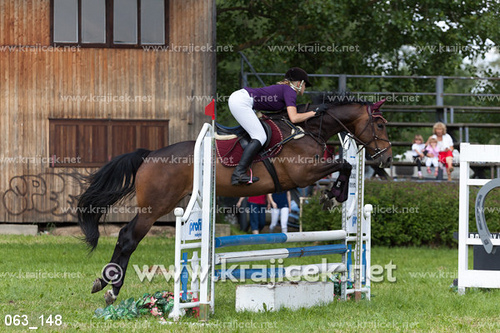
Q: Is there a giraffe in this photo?
A: No, there are no giraffes.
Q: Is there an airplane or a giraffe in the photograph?
A: No, there are no giraffes or airplanes.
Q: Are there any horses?
A: Yes, there is a horse.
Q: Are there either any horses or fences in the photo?
A: Yes, there is a horse.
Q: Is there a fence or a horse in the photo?
A: Yes, there is a horse.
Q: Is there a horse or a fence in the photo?
A: Yes, there is a horse.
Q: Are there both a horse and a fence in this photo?
A: Yes, there are both a horse and a fence.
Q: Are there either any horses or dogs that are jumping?
A: Yes, the horse is jumping.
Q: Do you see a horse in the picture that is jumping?
A: Yes, there is a horse that is jumping.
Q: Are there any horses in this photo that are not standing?
A: Yes, there is a horse that is jumping.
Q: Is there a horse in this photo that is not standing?
A: Yes, there is a horse that is jumping.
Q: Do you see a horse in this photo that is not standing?
A: Yes, there is a horse that is jumping .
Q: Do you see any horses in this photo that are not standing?
A: Yes, there is a horse that is jumping .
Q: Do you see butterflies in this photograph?
A: No, there are no butterflies.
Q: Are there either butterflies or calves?
A: No, there are no butterflies or calves.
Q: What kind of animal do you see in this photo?
A: The animal is a horse.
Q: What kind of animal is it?
A: The animal is a horse.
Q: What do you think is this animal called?
A: This is a horse.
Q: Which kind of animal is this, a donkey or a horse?
A: This is a horse.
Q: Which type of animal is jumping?
A: The animal is a horse.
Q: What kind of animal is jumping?
A: The animal is a horse.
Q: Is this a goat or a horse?
A: This is a horse.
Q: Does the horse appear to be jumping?
A: Yes, the horse is jumping.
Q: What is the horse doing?
A: The horse is jumping.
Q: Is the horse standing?
A: No, the horse is jumping.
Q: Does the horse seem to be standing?
A: No, the horse is jumping.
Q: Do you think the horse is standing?
A: No, the horse is jumping.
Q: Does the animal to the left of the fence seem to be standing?
A: No, the horse is jumping.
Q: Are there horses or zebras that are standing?
A: No, there is a horse but it is jumping.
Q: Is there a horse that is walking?
A: No, there is a horse but it is jumping.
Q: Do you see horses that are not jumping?
A: No, there is a horse but it is jumping.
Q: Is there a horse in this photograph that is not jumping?
A: No, there is a horse but it is jumping.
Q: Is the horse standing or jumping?
A: The horse is jumping.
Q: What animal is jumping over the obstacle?
A: The horse is jumping over the obstacle.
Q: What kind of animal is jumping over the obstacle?
A: The animal is a horse.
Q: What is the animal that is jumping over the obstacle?
A: The animal is a horse.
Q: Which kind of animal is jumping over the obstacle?
A: The animal is a horse.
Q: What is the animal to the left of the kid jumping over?
A: The horse is jumping over the obstacle.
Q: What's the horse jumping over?
A: The horse is jumping over the obstacle.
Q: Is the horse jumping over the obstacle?
A: Yes, the horse is jumping over the obstacle.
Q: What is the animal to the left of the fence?
A: The animal is a horse.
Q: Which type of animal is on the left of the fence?
A: The animal is a horse.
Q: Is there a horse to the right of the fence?
A: No, the horse is to the left of the fence.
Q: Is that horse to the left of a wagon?
A: No, the horse is to the left of the fence.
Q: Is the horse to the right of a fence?
A: No, the horse is to the left of a fence.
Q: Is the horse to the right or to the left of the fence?
A: The horse is to the left of the fence.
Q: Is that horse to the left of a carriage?
A: No, the horse is to the left of a child.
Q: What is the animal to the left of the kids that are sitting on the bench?
A: The animal is a horse.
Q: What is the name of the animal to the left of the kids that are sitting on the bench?
A: The animal is a horse.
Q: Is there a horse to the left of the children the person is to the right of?
A: Yes, there is a horse to the left of the kids.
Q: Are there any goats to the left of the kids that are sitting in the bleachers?
A: No, there is a horse to the left of the children.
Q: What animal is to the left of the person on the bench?
A: The animal is a horse.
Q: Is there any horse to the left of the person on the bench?
A: Yes, there is a horse to the left of the person.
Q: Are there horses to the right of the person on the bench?
A: No, the horse is to the left of the person.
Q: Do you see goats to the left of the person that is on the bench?
A: No, there is a horse to the left of the person.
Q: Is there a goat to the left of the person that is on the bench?
A: No, there is a horse to the left of the person.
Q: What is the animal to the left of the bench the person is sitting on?
A: The animal is a horse.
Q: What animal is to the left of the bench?
A: The animal is a horse.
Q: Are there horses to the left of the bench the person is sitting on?
A: Yes, there is a horse to the left of the bench.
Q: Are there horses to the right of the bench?
A: No, the horse is to the left of the bench.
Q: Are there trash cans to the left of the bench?
A: No, there is a horse to the left of the bench.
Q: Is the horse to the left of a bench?
A: Yes, the horse is to the left of a bench.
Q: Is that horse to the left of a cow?
A: No, the horse is to the left of a bench.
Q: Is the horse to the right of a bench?
A: No, the horse is to the left of a bench.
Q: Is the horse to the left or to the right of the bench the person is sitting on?
A: The horse is to the left of the bench.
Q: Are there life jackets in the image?
A: No, there are no life jackets.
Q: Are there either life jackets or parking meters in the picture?
A: No, there are no life jackets or parking meters.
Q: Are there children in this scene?
A: Yes, there is a child.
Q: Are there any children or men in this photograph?
A: Yes, there is a child.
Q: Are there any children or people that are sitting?
A: Yes, the child is sitting.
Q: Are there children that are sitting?
A: Yes, there is a child that is sitting.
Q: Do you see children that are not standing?
A: Yes, there is a child that is sitting .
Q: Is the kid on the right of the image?
A: Yes, the kid is on the right of the image.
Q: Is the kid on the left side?
A: No, the kid is on the right of the image.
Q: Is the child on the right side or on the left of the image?
A: The child is on the right of the image.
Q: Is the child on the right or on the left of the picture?
A: The child is on the right of the image.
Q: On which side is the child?
A: The child is on the right of the image.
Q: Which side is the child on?
A: The child is on the right of the image.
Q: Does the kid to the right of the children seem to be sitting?
A: Yes, the child is sitting.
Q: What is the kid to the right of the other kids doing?
A: The kid is sitting.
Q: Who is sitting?
A: The child is sitting.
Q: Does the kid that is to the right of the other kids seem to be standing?
A: No, the child is sitting.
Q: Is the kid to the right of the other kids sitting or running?
A: The child is sitting.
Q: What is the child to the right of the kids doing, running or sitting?
A: The kid is sitting.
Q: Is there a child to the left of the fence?
A: Yes, there is a child to the left of the fence.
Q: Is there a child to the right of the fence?
A: No, the child is to the left of the fence.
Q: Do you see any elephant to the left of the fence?
A: No, there is a child to the left of the fence.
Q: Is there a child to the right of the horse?
A: Yes, there is a child to the right of the horse.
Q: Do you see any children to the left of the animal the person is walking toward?
A: No, the child is to the right of the horse.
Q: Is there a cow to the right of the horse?
A: No, there is a child to the right of the horse.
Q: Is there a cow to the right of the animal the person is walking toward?
A: No, there is a child to the right of the horse.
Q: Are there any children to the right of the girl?
A: Yes, there is a child to the right of the girl.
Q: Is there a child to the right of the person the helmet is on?
A: Yes, there is a child to the right of the girl.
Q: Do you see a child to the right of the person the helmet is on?
A: Yes, there is a child to the right of the girl.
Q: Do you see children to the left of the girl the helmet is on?
A: No, the child is to the right of the girl.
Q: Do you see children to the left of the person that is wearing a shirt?
A: No, the child is to the right of the girl.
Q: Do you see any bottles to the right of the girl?
A: No, there is a child to the right of the girl.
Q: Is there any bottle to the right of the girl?
A: No, there is a child to the right of the girl.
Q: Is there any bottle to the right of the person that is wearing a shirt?
A: No, there is a child to the right of the girl.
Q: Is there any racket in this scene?
A: No, there are no rackets.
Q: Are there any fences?
A: Yes, there is a fence.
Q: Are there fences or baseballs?
A: Yes, there is a fence.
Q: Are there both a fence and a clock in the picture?
A: No, there is a fence but no clocks.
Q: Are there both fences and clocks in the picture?
A: No, there is a fence but no clocks.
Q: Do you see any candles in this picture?
A: No, there are no candles.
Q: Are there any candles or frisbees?
A: No, there are no candles or frisbees.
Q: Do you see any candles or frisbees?
A: No, there are no candles or frisbees.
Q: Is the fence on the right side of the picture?
A: Yes, the fence is on the right of the image.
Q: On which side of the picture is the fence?
A: The fence is on the right of the image.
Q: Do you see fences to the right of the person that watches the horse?
A: Yes, there is a fence to the right of the person.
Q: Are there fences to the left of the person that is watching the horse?
A: No, the fence is to the right of the person.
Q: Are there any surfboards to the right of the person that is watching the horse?
A: No, there is a fence to the right of the person.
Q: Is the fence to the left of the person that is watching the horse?
A: No, the fence is to the right of the person.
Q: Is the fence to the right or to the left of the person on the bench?
A: The fence is to the right of the person.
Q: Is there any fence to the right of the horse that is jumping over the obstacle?
A: Yes, there is a fence to the right of the horse.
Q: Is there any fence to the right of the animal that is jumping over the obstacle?
A: Yes, there is a fence to the right of the horse.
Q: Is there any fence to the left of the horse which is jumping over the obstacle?
A: No, the fence is to the right of the horse.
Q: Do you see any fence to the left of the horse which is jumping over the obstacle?
A: No, the fence is to the right of the horse.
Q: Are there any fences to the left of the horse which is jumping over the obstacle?
A: No, the fence is to the right of the horse.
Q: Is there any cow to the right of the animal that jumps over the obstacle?
A: No, there is a fence to the right of the horse.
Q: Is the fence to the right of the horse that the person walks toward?
A: Yes, the fence is to the right of the horse.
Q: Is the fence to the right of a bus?
A: No, the fence is to the right of the horse.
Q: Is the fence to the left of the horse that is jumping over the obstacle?
A: No, the fence is to the right of the horse.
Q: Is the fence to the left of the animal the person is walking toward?
A: No, the fence is to the right of the horse.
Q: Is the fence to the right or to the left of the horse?
A: The fence is to the right of the horse.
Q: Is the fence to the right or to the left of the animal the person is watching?
A: The fence is to the right of the horse.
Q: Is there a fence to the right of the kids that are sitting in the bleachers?
A: Yes, there is a fence to the right of the children.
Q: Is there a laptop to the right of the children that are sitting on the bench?
A: No, there is a fence to the right of the children.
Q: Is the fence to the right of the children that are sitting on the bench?
A: Yes, the fence is to the right of the kids.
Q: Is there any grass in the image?
A: Yes, there is grass.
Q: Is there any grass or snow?
A: Yes, there is grass.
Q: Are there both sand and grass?
A: No, there is grass but no sand.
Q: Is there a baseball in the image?
A: No, there are no baseballs.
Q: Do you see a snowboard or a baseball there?
A: No, there are no baseballs or snowboards.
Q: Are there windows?
A: Yes, there is a window.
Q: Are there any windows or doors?
A: Yes, there is a window.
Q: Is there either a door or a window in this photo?
A: Yes, there is a window.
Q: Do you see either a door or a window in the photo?
A: Yes, there is a window.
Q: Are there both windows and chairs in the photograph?
A: No, there is a window but no chairs.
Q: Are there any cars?
A: No, there are no cars.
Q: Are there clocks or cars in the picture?
A: No, there are no cars or clocks.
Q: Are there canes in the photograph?
A: No, there are no canes.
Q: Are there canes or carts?
A: No, there are no canes or carts.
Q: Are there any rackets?
A: No, there are no rackets.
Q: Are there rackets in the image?
A: No, there are no rackets.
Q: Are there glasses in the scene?
A: No, there are no glasses.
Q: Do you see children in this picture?
A: Yes, there are children.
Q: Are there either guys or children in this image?
A: Yes, there are children.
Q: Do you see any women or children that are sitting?
A: Yes, the children are sitting.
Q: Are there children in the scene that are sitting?
A: Yes, there are children that are sitting.